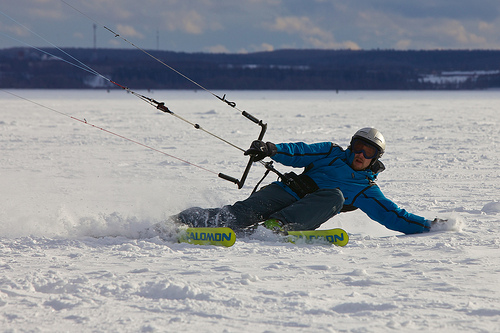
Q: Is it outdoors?
A: Yes, it is outdoors.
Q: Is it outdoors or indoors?
A: It is outdoors.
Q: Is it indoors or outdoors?
A: It is outdoors.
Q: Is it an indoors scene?
A: No, it is outdoors.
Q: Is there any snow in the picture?
A: Yes, there is snow.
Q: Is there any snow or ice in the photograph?
A: Yes, there is snow.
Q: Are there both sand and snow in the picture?
A: No, there is snow but no sand.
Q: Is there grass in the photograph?
A: No, there is no grass.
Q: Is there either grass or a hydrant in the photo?
A: No, there are no grass or fire hydrants.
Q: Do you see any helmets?
A: Yes, there is a helmet.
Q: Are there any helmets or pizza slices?
A: Yes, there is a helmet.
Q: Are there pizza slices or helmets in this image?
A: Yes, there is a helmet.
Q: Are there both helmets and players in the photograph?
A: No, there is a helmet but no players.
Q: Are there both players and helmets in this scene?
A: No, there is a helmet but no players.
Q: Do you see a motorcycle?
A: No, there are no motorcycles.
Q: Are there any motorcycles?
A: No, there are no motorcycles.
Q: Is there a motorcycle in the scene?
A: No, there are no motorcycles.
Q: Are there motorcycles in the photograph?
A: No, there are no motorcycles.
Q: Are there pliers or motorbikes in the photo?
A: No, there are no motorbikes or pliers.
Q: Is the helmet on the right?
A: Yes, the helmet is on the right of the image.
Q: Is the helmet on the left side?
A: No, the helmet is on the right of the image.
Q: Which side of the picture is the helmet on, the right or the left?
A: The helmet is on the right of the image.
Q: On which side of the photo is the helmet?
A: The helmet is on the right of the image.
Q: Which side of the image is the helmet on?
A: The helmet is on the right of the image.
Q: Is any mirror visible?
A: No, there are no mirrors.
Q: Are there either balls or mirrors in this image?
A: No, there are no mirrors or balls.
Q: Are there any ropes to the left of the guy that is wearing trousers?
A: Yes, there is a rope to the left of the guy.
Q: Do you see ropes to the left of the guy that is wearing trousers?
A: Yes, there is a rope to the left of the guy.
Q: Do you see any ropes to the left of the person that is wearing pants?
A: Yes, there is a rope to the left of the guy.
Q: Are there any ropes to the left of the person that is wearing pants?
A: Yes, there is a rope to the left of the guy.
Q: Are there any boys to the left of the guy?
A: No, there is a rope to the left of the guy.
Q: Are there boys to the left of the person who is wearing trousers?
A: No, there is a rope to the left of the guy.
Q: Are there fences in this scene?
A: No, there are no fences.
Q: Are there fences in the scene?
A: No, there are no fences.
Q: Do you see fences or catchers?
A: No, there are no fences or catchers.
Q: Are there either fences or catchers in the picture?
A: No, there are no fences or catchers.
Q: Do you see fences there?
A: No, there are no fences.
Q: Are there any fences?
A: No, there are no fences.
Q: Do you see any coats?
A: Yes, there is a coat.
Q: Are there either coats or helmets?
A: Yes, there is a coat.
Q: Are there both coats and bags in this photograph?
A: No, there is a coat but no bags.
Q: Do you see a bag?
A: No, there are no bags.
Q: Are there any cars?
A: No, there are no cars.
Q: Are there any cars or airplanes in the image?
A: No, there are no cars or airplanes.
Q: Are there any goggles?
A: Yes, there are goggles.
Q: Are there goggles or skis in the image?
A: Yes, there are goggles.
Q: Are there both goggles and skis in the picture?
A: Yes, there are both goggles and a ski.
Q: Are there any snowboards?
A: No, there are no snowboards.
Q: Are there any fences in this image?
A: No, there are no fences.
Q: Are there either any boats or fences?
A: No, there are no fences or boats.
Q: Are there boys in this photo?
A: No, there are no boys.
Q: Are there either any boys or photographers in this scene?
A: No, there are no boys or photographers.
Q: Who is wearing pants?
A: The guy is wearing pants.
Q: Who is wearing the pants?
A: The guy is wearing pants.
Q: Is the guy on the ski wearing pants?
A: Yes, the guy is wearing pants.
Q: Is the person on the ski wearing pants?
A: Yes, the guy is wearing pants.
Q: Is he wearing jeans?
A: No, the guy is wearing pants.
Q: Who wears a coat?
A: The guy wears a coat.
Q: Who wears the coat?
A: The guy wears a coat.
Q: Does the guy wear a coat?
A: Yes, the guy wears a coat.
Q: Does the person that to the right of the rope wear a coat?
A: Yes, the guy wears a coat.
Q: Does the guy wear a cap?
A: No, the guy wears a coat.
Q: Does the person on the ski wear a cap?
A: No, the guy wears a coat.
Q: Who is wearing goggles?
A: The guy is wearing goggles.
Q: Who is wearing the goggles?
A: The guy is wearing goggles.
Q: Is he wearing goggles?
A: Yes, the guy is wearing goggles.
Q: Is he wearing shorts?
A: No, the guy is wearing goggles.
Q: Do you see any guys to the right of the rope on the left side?
A: Yes, there is a guy to the right of the rope.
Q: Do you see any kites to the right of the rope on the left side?
A: No, there is a guy to the right of the rope.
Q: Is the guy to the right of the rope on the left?
A: Yes, the guy is to the right of the rope.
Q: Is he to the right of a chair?
A: No, the guy is to the right of the rope.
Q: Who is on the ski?
A: The guy is on the ski.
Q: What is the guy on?
A: The guy is on the ski.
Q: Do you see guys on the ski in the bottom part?
A: Yes, there is a guy on the ski.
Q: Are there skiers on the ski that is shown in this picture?
A: No, there is a guy on the ski.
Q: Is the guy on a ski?
A: Yes, the guy is on a ski.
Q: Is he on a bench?
A: No, the guy is on a ski.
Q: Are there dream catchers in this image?
A: No, there are no dream catchers.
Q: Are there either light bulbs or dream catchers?
A: No, there are no dream catchers or light bulbs.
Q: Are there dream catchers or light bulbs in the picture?
A: No, there are no dream catchers or light bulbs.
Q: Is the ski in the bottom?
A: Yes, the ski is in the bottom of the image.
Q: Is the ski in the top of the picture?
A: No, the ski is in the bottom of the image.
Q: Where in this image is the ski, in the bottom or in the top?
A: The ski is in the bottom of the image.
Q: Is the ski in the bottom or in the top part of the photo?
A: The ski is in the bottom of the image.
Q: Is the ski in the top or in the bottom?
A: The ski is in the bottom of the image.